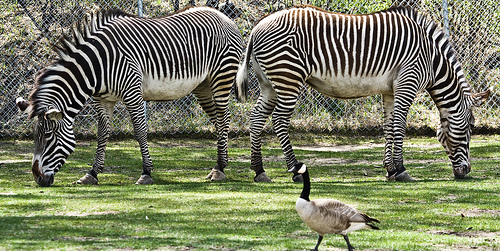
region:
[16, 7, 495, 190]
There are two zebras.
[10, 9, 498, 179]
The zebras are eating grass.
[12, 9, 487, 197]
The zebras face away from each other.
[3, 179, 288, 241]
There is grass on the ground.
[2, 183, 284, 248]
The grass is green.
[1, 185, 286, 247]
There is sunlight on the ground.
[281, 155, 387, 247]
There is a goose walking.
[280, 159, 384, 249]
The goose is a Canadian goose.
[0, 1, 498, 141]
There is a fence behind the zebras.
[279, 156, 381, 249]
The goose is walking left.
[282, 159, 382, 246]
a peacock without spread tailfeathers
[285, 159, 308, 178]
the head of a peacock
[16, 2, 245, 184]
a grazing zebra facing left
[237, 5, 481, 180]
grazing zebra facing right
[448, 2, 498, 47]
a chain link fence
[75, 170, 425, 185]
eight zebra hooves on the ground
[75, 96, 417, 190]
eight zebra legs standing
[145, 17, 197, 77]
black and white striped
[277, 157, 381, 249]
a peacock walking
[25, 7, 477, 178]
zebras ignoring each other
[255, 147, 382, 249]
Medium sized Canada Goose.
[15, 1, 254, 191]
Zebra cropping some grass.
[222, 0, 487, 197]
Zebra cropping some grass.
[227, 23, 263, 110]
Fluffy tail of a zebra.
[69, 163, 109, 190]
Medium sized zebra hoof.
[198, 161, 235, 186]
Medium sized split zebra hoof.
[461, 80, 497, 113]
Black and white zebra ear.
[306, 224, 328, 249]
Leg of a goose.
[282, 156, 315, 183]
Small goose head.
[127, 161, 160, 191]
Medium sized zebra hoof.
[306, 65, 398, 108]
white underbelly of zebra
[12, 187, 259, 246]
neatly manicured grass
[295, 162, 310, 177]
white patch on bird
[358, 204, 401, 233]
black bird's tail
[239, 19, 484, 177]
zebra stripes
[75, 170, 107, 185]
zebra hoof standing on grass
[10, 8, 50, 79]
portion of wire safety fence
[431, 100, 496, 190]
zebra eating freshly cutgrass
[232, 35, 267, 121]
black and white zebra's tail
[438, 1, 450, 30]
portion of blue pole attached to fence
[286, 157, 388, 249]
duck is walking near the zebras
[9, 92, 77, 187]
left zebra eating grass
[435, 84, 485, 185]
right zebra eating grass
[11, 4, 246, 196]
zebra on the left against the other zebra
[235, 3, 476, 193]
zebra on the right against the other zebra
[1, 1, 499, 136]
fence holding in animals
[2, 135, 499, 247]
grass the zebra are feeding on?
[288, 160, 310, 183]
duck with white and black head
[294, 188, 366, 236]
duck with white feathers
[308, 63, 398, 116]
zebras with white underbelly